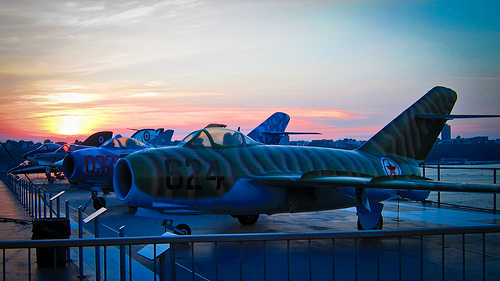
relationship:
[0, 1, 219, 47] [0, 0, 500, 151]
clouds floating in sky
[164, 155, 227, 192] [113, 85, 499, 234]
number painted on airplane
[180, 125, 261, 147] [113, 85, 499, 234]
cockpit of airplane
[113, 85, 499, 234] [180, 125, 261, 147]
airplane has cockpit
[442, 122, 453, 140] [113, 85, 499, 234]
building behind airplane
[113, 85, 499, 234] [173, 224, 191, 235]
airplane has front wheel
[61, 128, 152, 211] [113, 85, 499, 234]
airplane behind airplane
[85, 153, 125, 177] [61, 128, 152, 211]
number painted on airplane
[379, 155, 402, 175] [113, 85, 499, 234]
emblem located on airplane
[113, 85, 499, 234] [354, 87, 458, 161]
airplane has tail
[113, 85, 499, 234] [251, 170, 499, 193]
airplane has wing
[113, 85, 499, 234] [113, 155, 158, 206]
airplane has nose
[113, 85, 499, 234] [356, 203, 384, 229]
airplane has rear landing gear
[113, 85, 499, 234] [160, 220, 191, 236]
airplane has front landing gear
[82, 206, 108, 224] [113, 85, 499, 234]
sign in front of airplane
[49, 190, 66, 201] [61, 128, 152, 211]
sign in front of airplane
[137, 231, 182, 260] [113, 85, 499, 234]
sign in front of airplane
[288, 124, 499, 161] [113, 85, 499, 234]
city behind airplane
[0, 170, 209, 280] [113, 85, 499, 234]
railing in front of airplane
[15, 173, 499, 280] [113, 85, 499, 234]
concrete under airplane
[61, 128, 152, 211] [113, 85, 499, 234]
airplane next to airplane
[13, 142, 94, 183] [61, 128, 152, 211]
airplane next to airplane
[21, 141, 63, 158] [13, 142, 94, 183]
airplane next to airplane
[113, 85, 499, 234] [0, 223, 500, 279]
airplane behind fence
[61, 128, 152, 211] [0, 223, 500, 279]
airplane behind fence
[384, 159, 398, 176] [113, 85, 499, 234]
star located on airplane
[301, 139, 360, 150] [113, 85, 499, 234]
trees behind airplane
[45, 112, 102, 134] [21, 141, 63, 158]
sun behind airplane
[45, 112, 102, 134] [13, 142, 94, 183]
sun behind airplane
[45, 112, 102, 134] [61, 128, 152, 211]
sun behind airplane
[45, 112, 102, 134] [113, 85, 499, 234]
sun behind airplane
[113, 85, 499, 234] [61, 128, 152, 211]
airplane next to airplane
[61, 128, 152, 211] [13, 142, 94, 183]
airplane next to airplane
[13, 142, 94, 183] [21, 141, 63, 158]
airplane next to airplane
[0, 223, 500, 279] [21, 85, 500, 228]
fence around airplanes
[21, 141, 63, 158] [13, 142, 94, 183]
airplane behind airplane